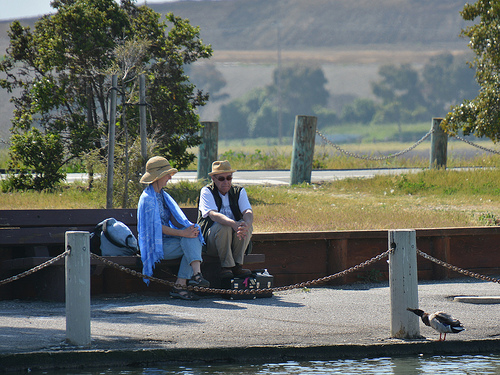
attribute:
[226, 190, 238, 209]
vest — dark 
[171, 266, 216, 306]
shoes — black 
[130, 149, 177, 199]
hat — tan 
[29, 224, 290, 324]
log — gray 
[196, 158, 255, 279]
man — arm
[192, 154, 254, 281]
man — hands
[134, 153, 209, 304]
woman — head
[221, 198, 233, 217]
shirt — white 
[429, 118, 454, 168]
pole — TAN 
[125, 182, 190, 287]
shirt — blue 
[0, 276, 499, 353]
path — concrete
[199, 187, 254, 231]
vest — green 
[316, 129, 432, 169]
fence — metal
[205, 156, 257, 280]
man — head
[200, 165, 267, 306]
man — feet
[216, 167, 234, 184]
glasses — sun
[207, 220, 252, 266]
pants — brown